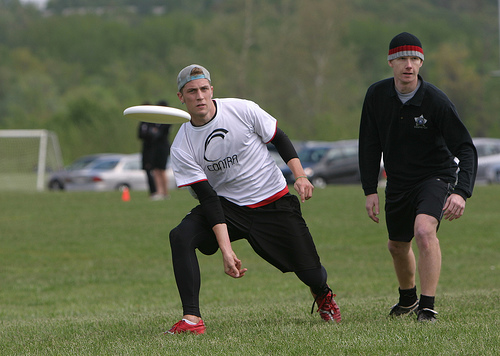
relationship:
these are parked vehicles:
[24, 151, 498, 208] [82, 164, 119, 215]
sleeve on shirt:
[193, 169, 242, 240] [170, 114, 300, 204]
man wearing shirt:
[355, 28, 480, 323] [357, 78, 477, 201]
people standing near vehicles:
[133, 93, 182, 200] [48, 131, 498, 198]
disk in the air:
[117, 94, 197, 129] [4, 7, 484, 343]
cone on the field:
[119, 180, 131, 203] [5, 181, 479, 341]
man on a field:
[355, 32, 480, 323] [5, 181, 479, 341]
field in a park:
[5, 181, 479, 341] [11, 30, 478, 338]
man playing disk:
[355, 32, 480, 323] [123, 105, 193, 125]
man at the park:
[164, 63, 342, 334] [7, 8, 484, 344]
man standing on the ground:
[355, 32, 480, 323] [6, 187, 476, 341]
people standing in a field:
[147, 97, 175, 199] [5, 181, 479, 341]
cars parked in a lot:
[43, 132, 483, 186] [61, 130, 481, 190]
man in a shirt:
[164, 63, 342, 334] [170, 98, 288, 207]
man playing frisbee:
[355, 32, 480, 323] [119, 99, 193, 125]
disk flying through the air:
[123, 105, 193, 125] [4, 7, 484, 343]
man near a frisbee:
[355, 32, 480, 323] [120, 99, 196, 127]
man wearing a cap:
[355, 28, 480, 323] [387, 24, 426, 59]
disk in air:
[123, 105, 193, 125] [12, 3, 485, 295]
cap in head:
[388, 37, 429, 60] [388, 41, 425, 80]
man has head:
[355, 28, 480, 323] [388, 41, 425, 80]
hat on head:
[173, 60, 213, 91] [157, 65, 342, 328]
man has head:
[164, 63, 342, 334] [157, 65, 342, 328]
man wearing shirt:
[126, 63, 342, 316] [166, 98, 296, 208]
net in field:
[3, 124, 60, 195] [12, 186, 486, 326]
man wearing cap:
[355, 28, 480, 323] [388, 32, 426, 60]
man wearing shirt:
[164, 63, 342, 334] [166, 98, 296, 208]